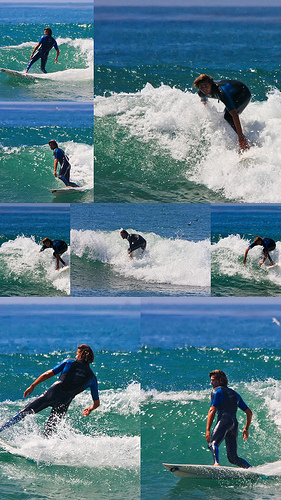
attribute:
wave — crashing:
[70, 227, 211, 288]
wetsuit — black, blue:
[206, 384, 247, 443]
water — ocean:
[93, 0, 280, 202]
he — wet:
[199, 364, 259, 464]